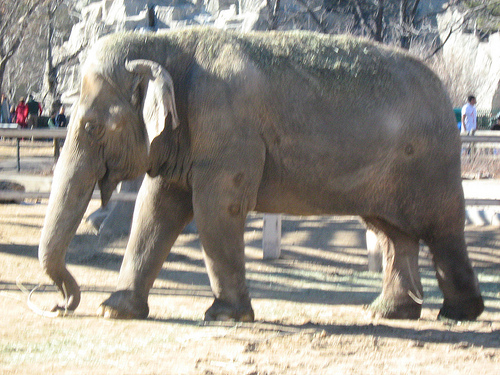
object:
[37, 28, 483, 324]
skin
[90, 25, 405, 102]
hair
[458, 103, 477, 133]
shirt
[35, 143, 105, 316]
trunk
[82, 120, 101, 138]
eye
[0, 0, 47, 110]
trees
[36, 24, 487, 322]
elephant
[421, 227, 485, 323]
legs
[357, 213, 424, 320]
legs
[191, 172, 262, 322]
legs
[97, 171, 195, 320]
legs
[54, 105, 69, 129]
people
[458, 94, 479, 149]
people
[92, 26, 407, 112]
mat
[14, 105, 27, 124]
jacket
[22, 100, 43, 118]
jacket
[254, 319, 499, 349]
shadow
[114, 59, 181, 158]
ear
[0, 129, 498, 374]
dirt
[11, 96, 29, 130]
woman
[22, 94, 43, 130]
man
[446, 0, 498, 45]
tree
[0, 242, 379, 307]
shadow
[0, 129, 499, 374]
ground